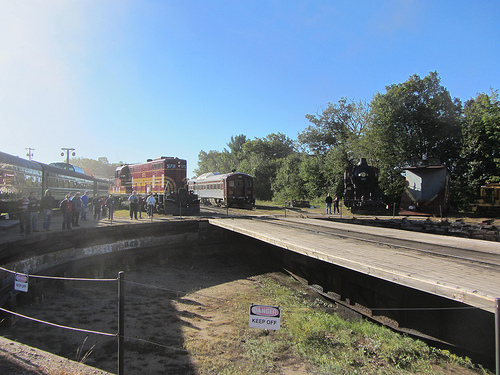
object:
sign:
[247, 302, 281, 332]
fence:
[0, 259, 499, 373]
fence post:
[110, 268, 128, 372]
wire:
[0, 263, 495, 371]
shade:
[5, 253, 279, 371]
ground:
[1, 252, 486, 374]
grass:
[4, 253, 480, 373]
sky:
[0, 1, 497, 178]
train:
[188, 170, 255, 208]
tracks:
[255, 202, 318, 214]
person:
[42, 188, 55, 231]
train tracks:
[207, 213, 499, 312]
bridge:
[208, 209, 500, 314]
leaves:
[361, 69, 464, 169]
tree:
[361, 69, 460, 192]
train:
[1, 148, 110, 222]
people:
[59, 193, 75, 230]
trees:
[271, 151, 308, 205]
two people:
[128, 190, 143, 220]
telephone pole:
[59, 147, 76, 170]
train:
[109, 157, 200, 216]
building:
[403, 164, 451, 210]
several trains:
[0, 152, 257, 220]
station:
[0, 110, 498, 373]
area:
[9, 224, 482, 375]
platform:
[1, 206, 195, 247]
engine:
[130, 156, 189, 195]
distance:
[17, 141, 216, 183]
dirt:
[13, 253, 249, 375]